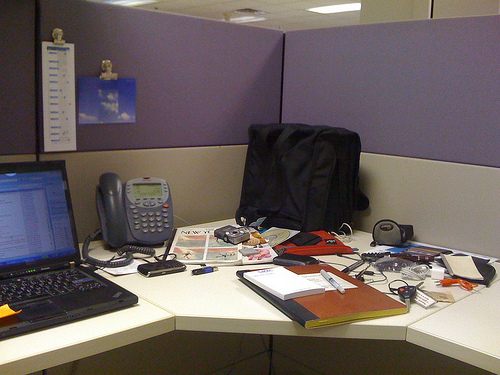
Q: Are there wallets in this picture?
A: No, there are no wallets.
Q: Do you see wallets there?
A: No, there are no wallets.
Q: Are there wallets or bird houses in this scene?
A: No, there are no wallets or bird houses.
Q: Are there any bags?
A: Yes, there is a bag.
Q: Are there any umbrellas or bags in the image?
A: Yes, there is a bag.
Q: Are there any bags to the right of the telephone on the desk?
A: Yes, there is a bag to the right of the telephone.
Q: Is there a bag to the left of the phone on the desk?
A: No, the bag is to the right of the phone.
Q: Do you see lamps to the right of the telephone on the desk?
A: No, there is a bag to the right of the phone.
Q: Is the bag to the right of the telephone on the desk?
A: Yes, the bag is to the right of the phone.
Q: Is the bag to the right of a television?
A: No, the bag is to the right of the phone.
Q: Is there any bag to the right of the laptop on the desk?
A: Yes, there is a bag to the right of the laptop.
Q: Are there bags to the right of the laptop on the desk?
A: Yes, there is a bag to the right of the laptop.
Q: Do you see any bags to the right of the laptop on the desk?
A: Yes, there is a bag to the right of the laptop.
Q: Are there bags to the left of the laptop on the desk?
A: No, the bag is to the right of the laptop.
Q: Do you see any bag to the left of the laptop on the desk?
A: No, the bag is to the right of the laptop.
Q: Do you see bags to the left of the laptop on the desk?
A: No, the bag is to the right of the laptop.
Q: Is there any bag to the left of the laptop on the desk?
A: No, the bag is to the right of the laptop.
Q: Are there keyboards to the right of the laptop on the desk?
A: No, there is a bag to the right of the laptop.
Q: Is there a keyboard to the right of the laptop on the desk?
A: No, there is a bag to the right of the laptop.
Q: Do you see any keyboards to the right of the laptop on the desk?
A: No, there is a bag to the right of the laptop.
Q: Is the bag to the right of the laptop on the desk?
A: Yes, the bag is to the right of the laptop.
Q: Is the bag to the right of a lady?
A: No, the bag is to the right of the laptop.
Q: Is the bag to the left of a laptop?
A: No, the bag is to the right of a laptop.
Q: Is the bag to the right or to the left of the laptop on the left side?
A: The bag is to the right of the laptop.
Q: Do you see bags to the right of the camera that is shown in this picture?
A: Yes, there is a bag to the right of the camera.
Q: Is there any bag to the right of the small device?
A: Yes, there is a bag to the right of the camera.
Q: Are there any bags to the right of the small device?
A: Yes, there is a bag to the right of the camera.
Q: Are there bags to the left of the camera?
A: No, the bag is to the right of the camera.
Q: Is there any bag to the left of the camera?
A: No, the bag is to the right of the camera.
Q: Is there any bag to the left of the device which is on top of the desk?
A: No, the bag is to the right of the camera.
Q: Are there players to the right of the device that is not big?
A: No, there is a bag to the right of the camera.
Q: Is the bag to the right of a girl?
A: No, the bag is to the right of the camera.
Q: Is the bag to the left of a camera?
A: No, the bag is to the right of a camera.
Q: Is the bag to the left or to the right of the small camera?
A: The bag is to the right of the camera.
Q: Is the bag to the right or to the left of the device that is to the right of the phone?
A: The bag is to the right of the camera.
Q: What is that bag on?
A: The bag is on the desk.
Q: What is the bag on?
A: The bag is on the desk.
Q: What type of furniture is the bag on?
A: The bag is on the desk.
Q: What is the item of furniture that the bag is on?
A: The piece of furniture is a desk.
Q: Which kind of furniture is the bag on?
A: The bag is on the desk.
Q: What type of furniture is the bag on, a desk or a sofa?
A: The bag is on a desk.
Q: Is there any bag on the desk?
A: Yes, there is a bag on the desk.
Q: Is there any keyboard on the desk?
A: No, there is a bag on the desk.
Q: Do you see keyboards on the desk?
A: No, there is a bag on the desk.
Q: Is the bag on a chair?
A: No, the bag is on a desk.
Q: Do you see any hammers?
A: No, there are no hammers.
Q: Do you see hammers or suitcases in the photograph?
A: No, there are no hammers or suitcases.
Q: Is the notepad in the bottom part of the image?
A: Yes, the notepad is in the bottom of the image.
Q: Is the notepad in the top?
A: No, the notepad is in the bottom of the image.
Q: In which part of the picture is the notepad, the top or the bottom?
A: The notepad is in the bottom of the image.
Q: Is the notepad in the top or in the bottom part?
A: The notepad is in the bottom of the image.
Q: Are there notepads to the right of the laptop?
A: Yes, there is a notepad to the right of the laptop.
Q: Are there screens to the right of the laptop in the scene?
A: No, there is a notepad to the right of the laptop.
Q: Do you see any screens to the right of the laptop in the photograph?
A: No, there is a notepad to the right of the laptop.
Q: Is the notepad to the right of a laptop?
A: Yes, the notepad is to the right of a laptop.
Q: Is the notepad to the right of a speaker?
A: No, the notepad is to the right of a laptop.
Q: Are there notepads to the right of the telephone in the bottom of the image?
A: Yes, there is a notepad to the right of the phone.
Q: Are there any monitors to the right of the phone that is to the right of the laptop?
A: No, there is a notepad to the right of the telephone.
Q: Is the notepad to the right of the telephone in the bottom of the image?
A: Yes, the notepad is to the right of the telephone.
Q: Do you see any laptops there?
A: Yes, there is a laptop.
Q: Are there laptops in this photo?
A: Yes, there is a laptop.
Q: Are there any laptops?
A: Yes, there is a laptop.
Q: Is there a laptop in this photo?
A: Yes, there is a laptop.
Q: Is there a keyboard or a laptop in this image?
A: Yes, there is a laptop.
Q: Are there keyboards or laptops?
A: Yes, there is a laptop.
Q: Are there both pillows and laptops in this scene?
A: No, there is a laptop but no pillows.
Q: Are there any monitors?
A: No, there are no monitors.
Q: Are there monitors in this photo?
A: No, there are no monitors.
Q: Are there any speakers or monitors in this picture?
A: No, there are no monitors or speakers.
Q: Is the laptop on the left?
A: Yes, the laptop is on the left of the image.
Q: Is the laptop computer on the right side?
A: No, the laptop computer is on the left of the image.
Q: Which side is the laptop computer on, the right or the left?
A: The laptop computer is on the left of the image.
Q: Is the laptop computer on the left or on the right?
A: The laptop computer is on the left of the image.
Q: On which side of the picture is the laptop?
A: The laptop is on the left of the image.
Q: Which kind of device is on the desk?
A: The device is a laptop.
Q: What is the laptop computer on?
A: The laptop computer is on the desk.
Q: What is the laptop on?
A: The laptop computer is on the desk.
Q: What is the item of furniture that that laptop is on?
A: The piece of furniture is a desk.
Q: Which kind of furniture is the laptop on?
A: The laptop is on the desk.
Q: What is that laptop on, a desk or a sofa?
A: The laptop is on a desk.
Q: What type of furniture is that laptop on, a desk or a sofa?
A: The laptop is on a desk.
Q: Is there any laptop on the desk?
A: Yes, there is a laptop on the desk.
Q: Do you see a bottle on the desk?
A: No, there is a laptop on the desk.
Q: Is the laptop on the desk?
A: Yes, the laptop is on the desk.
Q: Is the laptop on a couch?
A: No, the laptop is on the desk.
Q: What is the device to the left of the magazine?
A: The device is a laptop.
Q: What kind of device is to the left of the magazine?
A: The device is a laptop.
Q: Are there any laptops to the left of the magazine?
A: Yes, there is a laptop to the left of the magazine.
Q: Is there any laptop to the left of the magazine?
A: Yes, there is a laptop to the left of the magazine.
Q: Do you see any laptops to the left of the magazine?
A: Yes, there is a laptop to the left of the magazine.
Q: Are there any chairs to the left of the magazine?
A: No, there is a laptop to the left of the magazine.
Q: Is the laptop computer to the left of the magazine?
A: Yes, the laptop computer is to the left of the magazine.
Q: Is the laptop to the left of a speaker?
A: No, the laptop is to the left of the magazine.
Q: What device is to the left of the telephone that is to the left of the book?
A: The device is a laptop.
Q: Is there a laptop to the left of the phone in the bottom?
A: Yes, there is a laptop to the left of the telephone.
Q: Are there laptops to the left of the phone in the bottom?
A: Yes, there is a laptop to the left of the telephone.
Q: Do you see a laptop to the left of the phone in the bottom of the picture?
A: Yes, there is a laptop to the left of the telephone.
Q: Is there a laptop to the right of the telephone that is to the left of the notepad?
A: No, the laptop is to the left of the telephone.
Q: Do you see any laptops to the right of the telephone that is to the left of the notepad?
A: No, the laptop is to the left of the telephone.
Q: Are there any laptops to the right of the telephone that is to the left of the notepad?
A: No, the laptop is to the left of the telephone.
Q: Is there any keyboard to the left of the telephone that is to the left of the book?
A: No, there is a laptop to the left of the telephone.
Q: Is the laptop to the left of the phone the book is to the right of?
A: Yes, the laptop is to the left of the telephone.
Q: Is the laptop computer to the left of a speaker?
A: No, the laptop computer is to the left of the telephone.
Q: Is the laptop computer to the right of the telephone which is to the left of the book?
A: No, the laptop computer is to the left of the telephone.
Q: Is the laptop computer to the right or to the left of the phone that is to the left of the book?
A: The laptop computer is to the left of the telephone.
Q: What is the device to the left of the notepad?
A: The device is a laptop.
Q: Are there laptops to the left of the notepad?
A: Yes, there is a laptop to the left of the notepad.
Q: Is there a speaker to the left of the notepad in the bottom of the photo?
A: No, there is a laptop to the left of the notepad.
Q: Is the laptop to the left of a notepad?
A: Yes, the laptop is to the left of a notepad.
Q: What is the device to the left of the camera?
A: The device is a laptop.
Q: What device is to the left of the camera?
A: The device is a laptop.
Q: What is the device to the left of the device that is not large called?
A: The device is a laptop.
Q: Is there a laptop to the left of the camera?
A: Yes, there is a laptop to the left of the camera.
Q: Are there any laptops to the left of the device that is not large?
A: Yes, there is a laptop to the left of the camera.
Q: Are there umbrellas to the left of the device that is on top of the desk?
A: No, there is a laptop to the left of the camera.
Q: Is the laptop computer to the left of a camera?
A: Yes, the laptop computer is to the left of a camera.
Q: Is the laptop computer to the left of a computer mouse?
A: No, the laptop computer is to the left of a camera.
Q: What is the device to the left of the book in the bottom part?
A: The device is a laptop.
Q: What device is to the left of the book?
A: The device is a laptop.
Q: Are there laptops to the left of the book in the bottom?
A: Yes, there is a laptop to the left of the book.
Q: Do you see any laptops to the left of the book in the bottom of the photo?
A: Yes, there is a laptop to the left of the book.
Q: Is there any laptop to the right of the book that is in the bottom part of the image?
A: No, the laptop is to the left of the book.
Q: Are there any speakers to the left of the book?
A: No, there is a laptop to the left of the book.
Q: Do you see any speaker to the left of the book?
A: No, there is a laptop to the left of the book.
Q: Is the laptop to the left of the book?
A: Yes, the laptop is to the left of the book.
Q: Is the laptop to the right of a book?
A: No, the laptop is to the left of a book.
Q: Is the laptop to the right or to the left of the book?
A: The laptop is to the left of the book.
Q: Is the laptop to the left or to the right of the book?
A: The laptop is to the left of the book.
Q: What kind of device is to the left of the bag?
A: The device is a laptop.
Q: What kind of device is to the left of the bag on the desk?
A: The device is a laptop.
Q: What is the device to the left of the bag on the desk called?
A: The device is a laptop.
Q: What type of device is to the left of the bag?
A: The device is a laptop.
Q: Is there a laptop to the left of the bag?
A: Yes, there is a laptop to the left of the bag.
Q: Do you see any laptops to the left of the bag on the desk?
A: Yes, there is a laptop to the left of the bag.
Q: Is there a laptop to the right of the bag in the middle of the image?
A: No, the laptop is to the left of the bag.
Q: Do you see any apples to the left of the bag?
A: No, there is a laptop to the left of the bag.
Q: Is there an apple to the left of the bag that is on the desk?
A: No, there is a laptop to the left of the bag.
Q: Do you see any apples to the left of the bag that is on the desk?
A: No, there is a laptop to the left of the bag.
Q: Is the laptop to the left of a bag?
A: Yes, the laptop is to the left of a bag.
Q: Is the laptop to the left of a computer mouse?
A: No, the laptop is to the left of a bag.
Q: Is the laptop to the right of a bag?
A: No, the laptop is to the left of a bag.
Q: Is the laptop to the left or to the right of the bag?
A: The laptop is to the left of the bag.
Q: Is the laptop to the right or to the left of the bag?
A: The laptop is to the left of the bag.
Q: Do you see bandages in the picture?
A: No, there are no bandages.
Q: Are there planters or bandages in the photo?
A: No, there are no bandages or planters.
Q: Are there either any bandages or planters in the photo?
A: No, there are no bandages or planters.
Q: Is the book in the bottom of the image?
A: Yes, the book is in the bottom of the image.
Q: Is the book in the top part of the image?
A: No, the book is in the bottom of the image.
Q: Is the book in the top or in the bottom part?
A: The book is in the bottom of the image.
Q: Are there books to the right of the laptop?
A: Yes, there is a book to the right of the laptop.